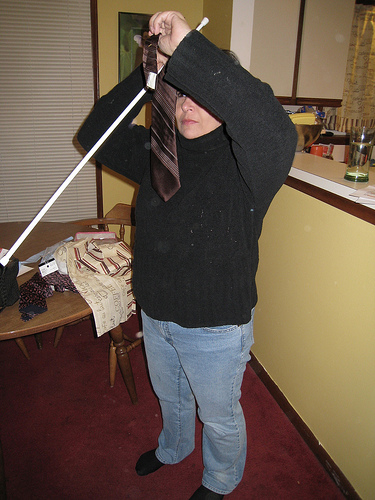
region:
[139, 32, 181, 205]
The person is holding a tie.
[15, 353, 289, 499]
The carpet is maroon.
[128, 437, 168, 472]
The sock is black.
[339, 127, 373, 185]
A glass on the counter.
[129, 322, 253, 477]
The lady is wearing blue jeans.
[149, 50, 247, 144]
head of a woman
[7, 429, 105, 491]
floor in front of lady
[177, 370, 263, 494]
pant leg of the pants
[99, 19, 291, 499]
a woman holding a tie over her head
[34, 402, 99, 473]
burgundy carpet on the floor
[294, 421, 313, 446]
dark brown wood trim on the wall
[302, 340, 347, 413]
a light yellow wall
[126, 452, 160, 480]
a black sock covering a foot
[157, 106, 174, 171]
brown and tan stripes on a tie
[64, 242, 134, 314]
fabric piled on a table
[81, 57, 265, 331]
a woman wearing a thick black sweater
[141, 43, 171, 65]
hands grasping a tie and a long white rod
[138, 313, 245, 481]
blue jeans covering two legs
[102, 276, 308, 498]
light blue jeans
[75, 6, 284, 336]
kid holding up a tie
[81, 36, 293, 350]
kid in a black sweater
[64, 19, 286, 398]
kid holding up his dad's tie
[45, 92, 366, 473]
kid standing on carpet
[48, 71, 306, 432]
kid getting dressed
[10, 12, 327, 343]
white stick on kid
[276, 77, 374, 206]
glass of water on counter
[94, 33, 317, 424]
kid tying a tie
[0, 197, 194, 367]
mess on the table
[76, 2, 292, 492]
Woman folding her husband's ties.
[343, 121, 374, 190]
Glass of water on bar for hydration.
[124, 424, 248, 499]
Woman going shoe less for indoor comfort.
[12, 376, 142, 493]
Red carpet for indoor comfort.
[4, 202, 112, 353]
Dining table with items on top of it.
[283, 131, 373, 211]
Bar between the dining room and kitchen.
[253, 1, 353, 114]
Cupboard for storing items in.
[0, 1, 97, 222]
Roll up blinds covering an exterior door.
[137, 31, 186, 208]
Men's necktie for dressing up.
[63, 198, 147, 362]
Dining room chair for sitting at the table.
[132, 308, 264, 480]
A pair of blue jeans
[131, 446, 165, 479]
A black sock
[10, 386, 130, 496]
A burgundy carpet floor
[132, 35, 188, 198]
A brown striped tie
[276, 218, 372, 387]
A pale yellow wall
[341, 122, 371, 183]
A glass on a counter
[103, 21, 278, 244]
A woman holding up a tie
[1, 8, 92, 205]
White shades on a window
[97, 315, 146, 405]
The wooden peg of a chair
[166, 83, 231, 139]
The bottom half of a woman's face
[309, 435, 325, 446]
small white spot on the wall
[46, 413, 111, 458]
red carpet on the floor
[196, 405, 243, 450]
wrinkles in woman's blue jeans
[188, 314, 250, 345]
pocket on blue jeans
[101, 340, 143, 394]
brown leg on table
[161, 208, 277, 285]
small spot on black sweater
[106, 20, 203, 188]
woman holding brown tie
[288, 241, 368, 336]
solid yellow wall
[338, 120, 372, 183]
small clear bottle on counter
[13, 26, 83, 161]
white blinds on the window